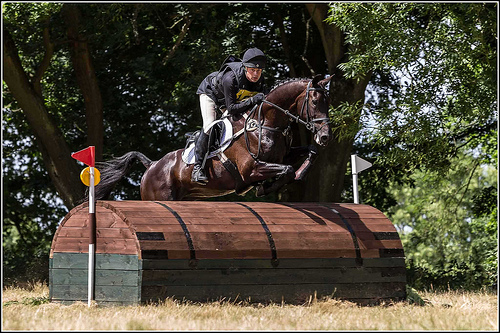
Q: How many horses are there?
A: One.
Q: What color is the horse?
A: Brown and black.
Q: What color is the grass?
A: Yellow.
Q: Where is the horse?
A: In the air.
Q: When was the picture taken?
A: Daytime.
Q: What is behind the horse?
A: The trees.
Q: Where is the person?
A: On the horse.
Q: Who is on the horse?
A: The rider.